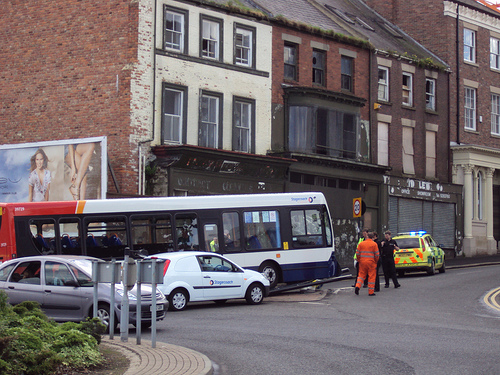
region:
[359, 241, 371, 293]
MAN WEARING A ORANGE SUIT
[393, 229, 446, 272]
YELLOW CAR ON THE STREET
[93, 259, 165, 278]
BOXES ON SOME POLES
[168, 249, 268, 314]
WHITE CAR IN THE TRAFFIC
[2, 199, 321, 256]
BUS ON THE STREET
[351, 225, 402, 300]
three people standing in a street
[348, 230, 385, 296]
man wearing orange jumpsuit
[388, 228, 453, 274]
yellow car parked in a street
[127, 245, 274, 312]
white car turning the corner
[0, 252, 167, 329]
gray car driving down a street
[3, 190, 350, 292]
bus that is red, white and blue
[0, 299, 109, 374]
green bushes growing along a street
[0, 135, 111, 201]
billboard on a building showing a woman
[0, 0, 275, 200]
apartment building with six windows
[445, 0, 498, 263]
building with pillars in front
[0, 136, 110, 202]
bill board on the side of a building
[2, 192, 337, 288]
long red and blue bus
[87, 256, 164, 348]
group of signs on the street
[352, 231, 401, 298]
group of men on the street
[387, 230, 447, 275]
emergency vehicle with lights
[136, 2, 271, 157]
white building with six windows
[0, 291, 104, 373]
group of bushes by the road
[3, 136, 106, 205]
feminine ad on a billboard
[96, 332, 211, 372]
brown stones on sidewalk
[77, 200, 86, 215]
orange stripe on bus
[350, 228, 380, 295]
A man in an orange jumpsuit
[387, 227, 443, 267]
A yellow and orange cab parked at a curb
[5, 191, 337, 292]
A large bus parked on the side of a road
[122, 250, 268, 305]
A white car next to a bus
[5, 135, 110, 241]
A billboard on the side of a wall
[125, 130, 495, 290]
A building on a city block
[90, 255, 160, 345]
Four metal street signs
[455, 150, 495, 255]
Columns on the front of a building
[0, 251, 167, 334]
A gray car parked on a city street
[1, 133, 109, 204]
billboard advertisement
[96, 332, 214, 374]
circular brick paving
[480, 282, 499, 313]
yellow solid double lines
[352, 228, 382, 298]
man wearing an orange jumpsuit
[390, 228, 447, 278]
neon yellow vehicle with flasher light bar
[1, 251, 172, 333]
four door vehicle going around traffic circle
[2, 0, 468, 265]
three story brick building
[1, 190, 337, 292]
red, white and blue bus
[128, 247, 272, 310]
white car with blue lettering on the door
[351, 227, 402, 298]
two men talking to each other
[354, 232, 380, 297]
the orange clothes on the man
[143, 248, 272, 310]
the white car next to the bus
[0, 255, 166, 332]
the gray car next to the white car